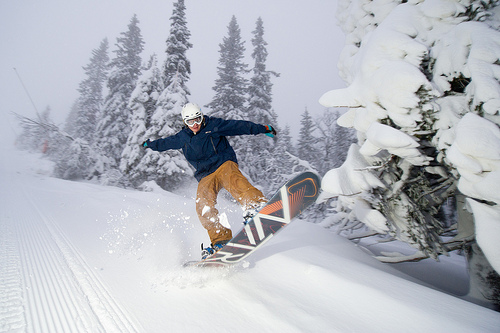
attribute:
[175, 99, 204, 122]
helmet — white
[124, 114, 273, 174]
top — blue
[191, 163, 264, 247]
pants — yellow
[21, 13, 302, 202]
trees — snow covered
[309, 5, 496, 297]
tree — snow covered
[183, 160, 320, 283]
snowboard — tilted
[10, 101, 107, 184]
tree — fallen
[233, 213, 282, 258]
stripes — white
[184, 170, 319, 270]
snowboard — orange, black, white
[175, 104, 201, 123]
helmet — white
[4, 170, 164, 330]
lines — horizontal, vertical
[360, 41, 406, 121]
snow — heavy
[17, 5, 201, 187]
trees — tall, evergreen, narrow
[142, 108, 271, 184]
jacket — blue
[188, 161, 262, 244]
pants — brown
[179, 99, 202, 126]
helmet — white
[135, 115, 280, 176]
jacket — blue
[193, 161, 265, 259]
snow pants — brown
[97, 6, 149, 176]
pine tree — tall, skinny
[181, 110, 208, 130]
googles — white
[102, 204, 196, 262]
snow — little bits